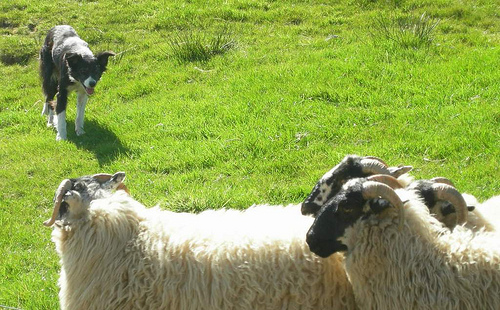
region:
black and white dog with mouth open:
[36, 19, 137, 152]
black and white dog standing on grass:
[21, 22, 131, 147]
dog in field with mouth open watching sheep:
[31, 18, 121, 145]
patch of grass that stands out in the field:
[163, 23, 235, 65]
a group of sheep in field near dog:
[40, 155, 498, 308]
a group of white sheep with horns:
[20, 153, 497, 309]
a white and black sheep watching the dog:
[42, 170, 359, 309]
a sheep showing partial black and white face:
[294, 150, 390, 225]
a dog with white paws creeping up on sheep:
[34, 18, 111, 148]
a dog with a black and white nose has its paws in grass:
[31, 19, 119, 143]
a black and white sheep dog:
[39, 23, 112, 143]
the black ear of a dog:
[98, 50, 114, 63]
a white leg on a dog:
[74, 90, 87, 137]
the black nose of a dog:
[89, 79, 97, 87]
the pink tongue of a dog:
[85, 86, 95, 95]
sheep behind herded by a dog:
[46, 153, 498, 309]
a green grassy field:
[0, 1, 497, 309]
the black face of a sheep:
[303, 176, 367, 259]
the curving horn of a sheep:
[364, 180, 407, 232]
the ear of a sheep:
[101, 171, 125, 191]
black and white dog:
[39, 19, 112, 143]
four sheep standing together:
[40, 165, 472, 309]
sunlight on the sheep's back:
[131, 179, 313, 263]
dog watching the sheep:
[23, 18, 113, 142]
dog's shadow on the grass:
[53, 120, 130, 172]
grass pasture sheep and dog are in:
[6, 10, 477, 308]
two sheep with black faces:
[297, 156, 491, 309]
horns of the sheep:
[36, 163, 465, 257]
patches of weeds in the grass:
[3, 11, 228, 66]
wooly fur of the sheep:
[83, 186, 498, 308]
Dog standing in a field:
[39, 23, 116, 144]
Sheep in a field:
[41, 170, 498, 307]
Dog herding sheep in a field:
[38, 24, 498, 307]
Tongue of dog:
[81, 88, 100, 95]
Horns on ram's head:
[364, 174, 403, 221]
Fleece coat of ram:
[48, 194, 352, 309]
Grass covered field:
[5, 2, 497, 307]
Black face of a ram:
[299, 179, 381, 257]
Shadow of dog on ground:
[49, 117, 131, 167]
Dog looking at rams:
[39, 22, 494, 309]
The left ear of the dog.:
[65, 52, 79, 67]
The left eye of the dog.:
[77, 68, 89, 75]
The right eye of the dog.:
[93, 69, 102, 74]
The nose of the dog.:
[87, 78, 94, 85]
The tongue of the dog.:
[88, 88, 92, 93]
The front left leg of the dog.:
[56, 80, 71, 144]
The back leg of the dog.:
[41, 83, 54, 122]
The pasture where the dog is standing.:
[10, 6, 496, 205]